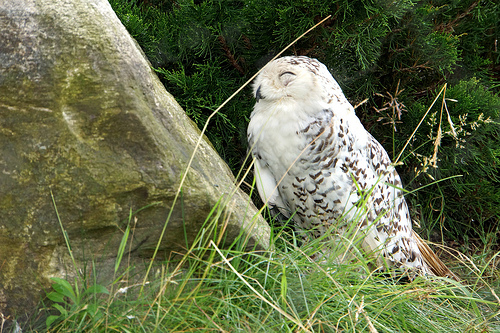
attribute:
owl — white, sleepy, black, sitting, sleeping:
[241, 63, 391, 193]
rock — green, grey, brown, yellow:
[19, 16, 155, 166]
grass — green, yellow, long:
[257, 246, 316, 293]